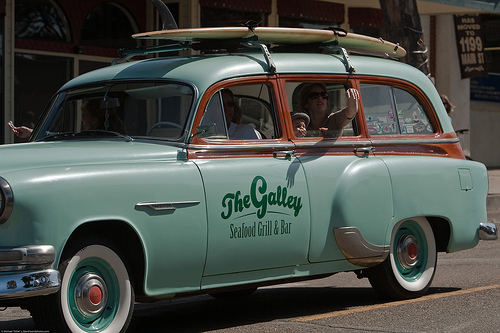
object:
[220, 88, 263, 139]
man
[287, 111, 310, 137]
child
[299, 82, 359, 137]
woman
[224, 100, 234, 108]
sunglasses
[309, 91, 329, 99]
sunglasses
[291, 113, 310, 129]
hat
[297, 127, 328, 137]
hands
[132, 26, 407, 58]
surfboard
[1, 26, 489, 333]
car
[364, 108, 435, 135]
stickers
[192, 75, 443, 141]
back window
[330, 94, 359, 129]
arm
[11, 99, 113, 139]
person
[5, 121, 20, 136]
something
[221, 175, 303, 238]
writing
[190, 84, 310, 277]
door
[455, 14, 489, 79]
sign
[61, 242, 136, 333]
tire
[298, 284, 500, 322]
line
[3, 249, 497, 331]
road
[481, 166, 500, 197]
sidewalk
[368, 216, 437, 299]
back tire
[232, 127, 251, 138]
white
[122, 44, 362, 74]
surfboard racks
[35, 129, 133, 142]
windshield wipers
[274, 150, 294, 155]
door handle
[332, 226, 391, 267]
fender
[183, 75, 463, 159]
trim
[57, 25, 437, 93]
roof